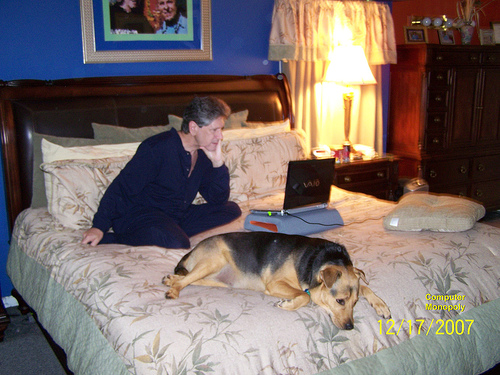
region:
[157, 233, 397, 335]
dog laying on a bed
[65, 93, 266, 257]
older woman sitting on a bed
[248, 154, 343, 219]
black Sony Vaio laptop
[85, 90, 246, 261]
woman in a long sleeved dark blue shirt and dark blue pants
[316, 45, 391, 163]
lamp that is on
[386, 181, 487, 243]
pillow hanging off bed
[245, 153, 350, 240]
laptop sitting on a blue cushion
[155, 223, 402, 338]
light brown and black dog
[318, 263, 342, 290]
brown floppy ear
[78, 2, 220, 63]
bottom half of artwork hanging on the wall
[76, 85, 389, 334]
a lady and her dog on the bed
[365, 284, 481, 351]
picture was taken in 2007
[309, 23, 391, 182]
a bright lamp on the nightstand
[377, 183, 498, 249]
a white square cushion on the bed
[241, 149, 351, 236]
a laptop resting on the bed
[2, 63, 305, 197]
a wood and leather headboard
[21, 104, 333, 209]
a group of pillows on the bed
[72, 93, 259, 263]
an elderly woman in her pajamas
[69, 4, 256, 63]
a gold framed picture hanging on the wall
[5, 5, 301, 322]
a bedroom wall painted blue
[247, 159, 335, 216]
A black laptop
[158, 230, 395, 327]
A black and brown dog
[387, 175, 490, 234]
A square cushion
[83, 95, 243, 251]
A person with grey hair wearing blue pajamas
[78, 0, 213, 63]
A framed photograph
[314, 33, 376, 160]
A turned on lamp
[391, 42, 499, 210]
A wooden armoire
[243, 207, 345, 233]
A grey laptop stand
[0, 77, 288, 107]
A brown wooden headboard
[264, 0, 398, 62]
A floral window valence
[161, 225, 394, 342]
Dog lying on a bed.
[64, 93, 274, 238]
Man sitting on a bed.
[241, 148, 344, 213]
Laptop in front of the man.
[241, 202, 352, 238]
The laptop stand is light blue.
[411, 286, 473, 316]
Computer Monopoly on the photo.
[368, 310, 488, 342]
Date of the photo.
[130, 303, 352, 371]
Leaf pattern on the blanket.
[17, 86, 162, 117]
The bed frame is brown.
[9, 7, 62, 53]
The wall is blue.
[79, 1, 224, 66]
Picture above the bed.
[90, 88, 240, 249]
the man is on the bed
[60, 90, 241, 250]
the man is wearing blue pajamas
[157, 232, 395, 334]
the dog is on the bed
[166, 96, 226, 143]
the man has gray hair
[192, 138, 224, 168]
the man's hand is on his chin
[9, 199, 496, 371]
the bedspread is flowery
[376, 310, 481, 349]
the date is 12/17/2007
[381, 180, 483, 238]
the pillow is at the end of the bed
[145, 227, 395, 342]
the dog is not sleeping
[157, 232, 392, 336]
the dog is black and tan